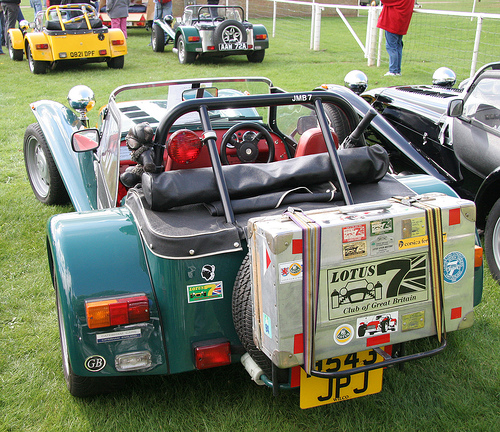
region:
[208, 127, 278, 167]
The steering wheel of the buggy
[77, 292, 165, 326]
The tail lights of the buggy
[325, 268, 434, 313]
The sticker with the word Lotus on it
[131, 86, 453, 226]
The roll cage of the buggy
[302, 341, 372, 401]
The license plate of the buggy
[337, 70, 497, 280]
The black buggy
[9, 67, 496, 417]
The closest green buggy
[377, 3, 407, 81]
The man standing in a red jacket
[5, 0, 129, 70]
The bright yellow buggy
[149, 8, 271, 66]
The green buggy that is further away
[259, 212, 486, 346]
stickers on a suitcase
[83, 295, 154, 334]
indicator lights on the rear of a car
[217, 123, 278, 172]
a vehicle steering wheel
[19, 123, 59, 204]
the front wheel of a vehicle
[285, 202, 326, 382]
a strap securing a suitcase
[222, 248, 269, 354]
a spare tire on a vehicle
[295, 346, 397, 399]
a yellow and black license plat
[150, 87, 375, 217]
a black roll bar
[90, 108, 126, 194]
side window of a vehicle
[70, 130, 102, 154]
side view mirror on a vehicle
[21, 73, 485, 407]
a small green car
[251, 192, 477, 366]
suitcase on the back of a car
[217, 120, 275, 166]
a black steering wheel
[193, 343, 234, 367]
a red tail light on a car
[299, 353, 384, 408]
a yellow license plate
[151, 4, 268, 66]
a small green car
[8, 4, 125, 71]
a small yellow car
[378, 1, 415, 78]
a person in a red jacket and jeans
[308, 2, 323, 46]
a white fence post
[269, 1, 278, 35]
a white fence post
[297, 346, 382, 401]
a yellow license plate on the car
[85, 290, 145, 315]
the turning signal on the car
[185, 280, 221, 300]
a sticker on the car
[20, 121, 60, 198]
the front tire of the car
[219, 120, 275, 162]
the steering wheel of the car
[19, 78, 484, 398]
a green car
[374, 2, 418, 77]
a person standing wearing a red shirt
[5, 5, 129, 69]
a yellow car parked in the grass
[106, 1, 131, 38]
a person wearing pink pants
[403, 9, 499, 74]
a white fence